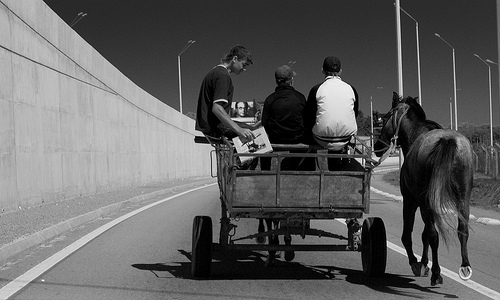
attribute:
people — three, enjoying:
[194, 44, 361, 143]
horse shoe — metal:
[458, 265, 474, 280]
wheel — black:
[187, 213, 216, 279]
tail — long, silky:
[428, 136, 466, 250]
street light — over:
[71, 8, 92, 24]